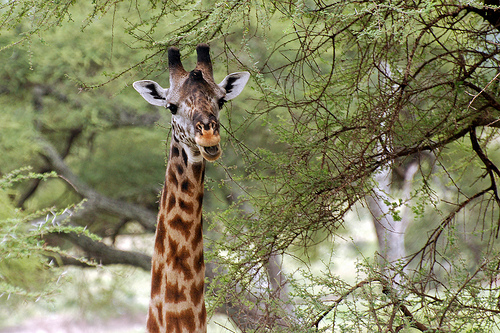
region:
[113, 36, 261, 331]
The giraffe has two ears.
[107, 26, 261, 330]
The giraffe's ears are pointed.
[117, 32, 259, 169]
The giraffe has two eyes.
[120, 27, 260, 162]
The giraffe's eyes are open.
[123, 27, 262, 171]
The giraffe's mouth is opened slightly.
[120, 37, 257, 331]
The giraffe is brown and tan.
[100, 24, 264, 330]
The giraffe is spotted.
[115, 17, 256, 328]
The giraffe has a long neck.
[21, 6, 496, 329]
Giraffe is standing amid tree limbs.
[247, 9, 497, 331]
The tree limbs are spindly.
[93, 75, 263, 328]
a giraffe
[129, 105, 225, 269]
a giraffe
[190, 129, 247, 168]
giraffee's open mouth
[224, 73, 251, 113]
giraffee's left ear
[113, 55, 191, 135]
giraffee's right ear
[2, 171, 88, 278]
green leaves on left of picture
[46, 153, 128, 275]
two wooden branches in background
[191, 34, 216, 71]
giraffee's left horn on top of his head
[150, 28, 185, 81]
giraffee's horn on right side of his head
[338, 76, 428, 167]
brown dying leaves on branches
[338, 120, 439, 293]
large wooden tree trunk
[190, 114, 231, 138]
giraffee's nose located above mouth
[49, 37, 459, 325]
picture taken outdoors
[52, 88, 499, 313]
picture taken during the day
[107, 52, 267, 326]
a single giraffe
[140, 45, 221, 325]
the giraffe is standing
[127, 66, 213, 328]
the giraffe has brown spots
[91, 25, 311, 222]
the giraffe has two horns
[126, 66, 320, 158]
the giraffe's eyes are black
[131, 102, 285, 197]
the giraffe's mouth is open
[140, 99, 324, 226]
the giraffe is eating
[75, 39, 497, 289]
trees around the giraffe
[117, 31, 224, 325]
giraffe standing among tree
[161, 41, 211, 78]
horns on giraffe head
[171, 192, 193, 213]
brown spot on giraffe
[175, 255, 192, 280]
brown spot on giraffe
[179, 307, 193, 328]
brown spot on giraffe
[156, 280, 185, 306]
brown spot on giraffe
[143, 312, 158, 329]
brown spot on giraffe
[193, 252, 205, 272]
brown spot on giraffe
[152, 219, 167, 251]
brown spot on giraffe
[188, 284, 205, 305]
brown spot on giraffe